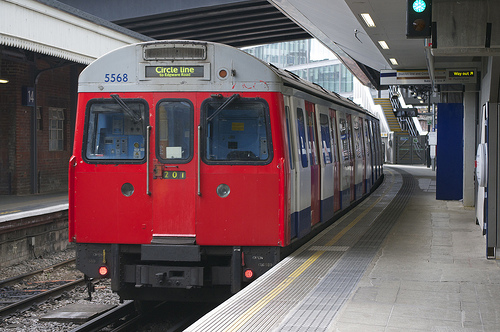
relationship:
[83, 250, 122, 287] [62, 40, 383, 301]
light on front train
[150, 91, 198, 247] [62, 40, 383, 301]
door on train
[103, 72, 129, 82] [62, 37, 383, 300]
blue numbers on train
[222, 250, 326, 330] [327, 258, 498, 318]
lines on ground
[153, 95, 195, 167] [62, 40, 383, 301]
window on train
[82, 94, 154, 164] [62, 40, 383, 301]
window on train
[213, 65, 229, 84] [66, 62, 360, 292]
lights on train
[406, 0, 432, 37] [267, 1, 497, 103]
light on roof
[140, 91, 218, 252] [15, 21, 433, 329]
door on train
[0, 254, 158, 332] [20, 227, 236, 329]
railway with gravel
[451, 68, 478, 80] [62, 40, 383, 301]
sign on train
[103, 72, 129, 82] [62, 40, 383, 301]
blue numbers on train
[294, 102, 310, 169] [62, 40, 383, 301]
window on train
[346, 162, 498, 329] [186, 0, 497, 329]
grey stone on train platform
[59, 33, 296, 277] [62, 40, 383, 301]
front on train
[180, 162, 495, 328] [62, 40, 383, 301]
walkway by train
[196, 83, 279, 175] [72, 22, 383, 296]
window on train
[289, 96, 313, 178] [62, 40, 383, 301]
window on train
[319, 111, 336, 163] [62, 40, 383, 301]
window on train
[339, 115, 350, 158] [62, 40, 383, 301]
window on train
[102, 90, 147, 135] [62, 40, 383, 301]
wiper on train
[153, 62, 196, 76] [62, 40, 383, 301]
words on train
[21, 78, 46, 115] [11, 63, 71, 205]
number on wall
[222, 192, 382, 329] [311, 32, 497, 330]
yellow line on train terminal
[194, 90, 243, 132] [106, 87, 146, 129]
wiper on wiper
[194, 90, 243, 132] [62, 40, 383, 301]
wiper on train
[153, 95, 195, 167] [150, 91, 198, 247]
window on door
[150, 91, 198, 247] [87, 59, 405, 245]
door on train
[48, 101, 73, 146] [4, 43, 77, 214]
window on side of building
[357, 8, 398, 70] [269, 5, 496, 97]
lights on ceiling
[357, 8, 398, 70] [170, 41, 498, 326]
lights on train platform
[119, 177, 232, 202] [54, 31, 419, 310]
headlights on front of train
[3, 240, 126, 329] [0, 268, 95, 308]
gravel between tracks